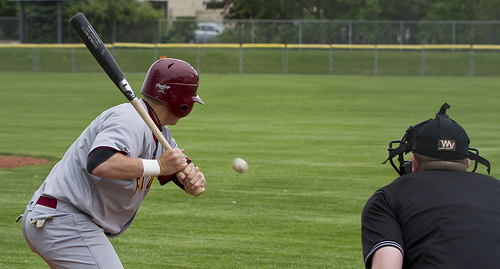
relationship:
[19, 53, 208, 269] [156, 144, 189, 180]
batter has hand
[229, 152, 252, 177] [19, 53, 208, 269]
ball flying towards batter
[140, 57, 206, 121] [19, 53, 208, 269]
helmet worn on batter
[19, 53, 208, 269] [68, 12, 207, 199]
batter about to swing bat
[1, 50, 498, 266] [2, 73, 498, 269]
grass growing on field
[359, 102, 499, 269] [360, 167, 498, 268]
umpire wearing shirt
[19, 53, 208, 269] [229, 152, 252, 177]
batter striking ball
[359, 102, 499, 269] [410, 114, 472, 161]
umpire wearing hat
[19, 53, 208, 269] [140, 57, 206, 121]
batter wearing helmet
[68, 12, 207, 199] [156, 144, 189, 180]
bat held in hand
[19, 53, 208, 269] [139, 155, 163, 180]
batter wearing sweat band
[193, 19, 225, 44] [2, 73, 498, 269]
car outside of field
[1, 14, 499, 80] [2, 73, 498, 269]
fence around field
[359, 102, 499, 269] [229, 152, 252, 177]
umpire watching ball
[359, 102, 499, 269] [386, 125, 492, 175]
umpire wearing mask